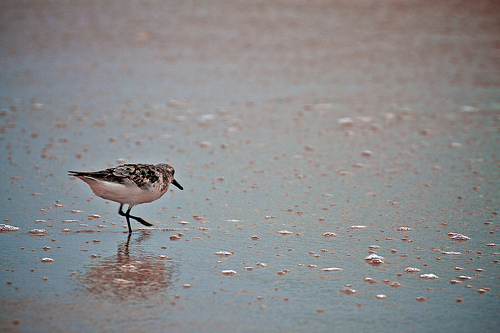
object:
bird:
[68, 154, 198, 234]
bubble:
[335, 104, 364, 141]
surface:
[229, 67, 465, 286]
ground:
[27, 98, 440, 333]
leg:
[118, 203, 141, 236]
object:
[320, 258, 345, 275]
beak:
[174, 178, 188, 193]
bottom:
[99, 175, 171, 212]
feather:
[92, 170, 119, 184]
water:
[90, 91, 146, 137]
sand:
[269, 95, 287, 122]